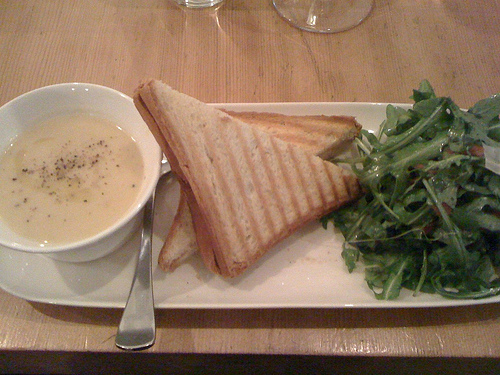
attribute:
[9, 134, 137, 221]
pepper — black, sprinkled, flecks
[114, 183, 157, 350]
handle — silver, metal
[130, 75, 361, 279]
sandwich — toasted, white, tan, halves, grilled, triangles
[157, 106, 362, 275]
sandwich — grilled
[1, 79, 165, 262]
bowl — white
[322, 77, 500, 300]
salad — green, leafy, vegetables, oiled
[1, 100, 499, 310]
plate — white, ceramic, narrow, large, rounded, oval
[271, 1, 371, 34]
glass — clear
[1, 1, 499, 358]
table — smooth, wooden, wood, brown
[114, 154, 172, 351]
spoon — silver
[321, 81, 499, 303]
lettuce — green, leaves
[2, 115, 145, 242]
soup — yellow, white, creamy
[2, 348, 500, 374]
edge — brown